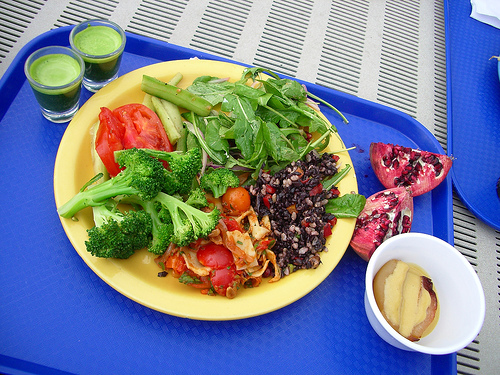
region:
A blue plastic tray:
[2, 21, 457, 373]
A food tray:
[444, 1, 497, 227]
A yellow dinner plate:
[50, 57, 358, 322]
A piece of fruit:
[369, 141, 454, 194]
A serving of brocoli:
[58, 148, 239, 258]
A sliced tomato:
[93, 105, 172, 176]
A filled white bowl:
[364, 230, 485, 355]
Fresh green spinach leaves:
[196, 66, 351, 171]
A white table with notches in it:
[1, 0, 499, 374]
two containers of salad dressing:
[21, 13, 123, 124]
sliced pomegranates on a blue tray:
[353, 138, 443, 231]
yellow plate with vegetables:
[83, 68, 358, 319]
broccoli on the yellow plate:
[76, 166, 203, 241]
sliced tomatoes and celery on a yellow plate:
[88, 79, 188, 146]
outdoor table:
[291, 2, 435, 65]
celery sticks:
[163, 77, 187, 137]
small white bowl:
[365, 232, 485, 349]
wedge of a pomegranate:
[370, 139, 453, 199]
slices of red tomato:
[94, 108, 170, 172]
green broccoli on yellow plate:
[68, 143, 223, 253]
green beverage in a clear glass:
[25, 45, 82, 122]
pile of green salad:
[186, 78, 318, 160]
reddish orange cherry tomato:
[223, 185, 250, 215]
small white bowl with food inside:
[363, 228, 485, 361]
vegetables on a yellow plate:
[50, 59, 357, 319]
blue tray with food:
[0, 15, 477, 372]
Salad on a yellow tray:
[71, 69, 353, 306]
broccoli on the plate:
[66, 147, 226, 268]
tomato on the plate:
[88, 96, 172, 172]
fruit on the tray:
[347, 124, 448, 256]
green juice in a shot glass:
[18, 43, 95, 117]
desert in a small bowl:
[383, 250, 449, 335]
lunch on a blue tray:
[12, 23, 498, 349]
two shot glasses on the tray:
[16, 16, 154, 118]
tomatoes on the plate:
[79, 90, 155, 141]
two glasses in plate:
[28, 13, 155, 107]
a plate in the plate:
[51, 54, 315, 336]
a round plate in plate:
[56, 68, 339, 300]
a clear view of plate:
[24, 264, 244, 370]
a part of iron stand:
[218, 7, 421, 99]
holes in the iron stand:
[259, 13, 310, 73]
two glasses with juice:
[4, 11, 157, 133]